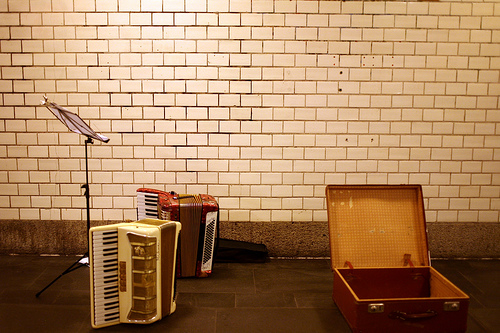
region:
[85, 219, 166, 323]
accordion on the ground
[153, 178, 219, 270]
brown accordion on the ground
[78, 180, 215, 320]
two accordions on the ground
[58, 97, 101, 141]
music sheet stand on ground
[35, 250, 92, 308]
bottom stand for pole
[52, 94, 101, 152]
white paper on music sheet stand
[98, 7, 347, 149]
white tile wall in the background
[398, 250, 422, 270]
brown latch on case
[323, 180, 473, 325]
brown suit case opened up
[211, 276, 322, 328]
grey stones on ground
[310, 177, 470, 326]
case for an instrument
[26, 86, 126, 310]
stand for sheet music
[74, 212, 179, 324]
keyboard to play music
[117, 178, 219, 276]
keyboard to play music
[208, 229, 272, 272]
sleeve to place instrument in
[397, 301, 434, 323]
handle on suitcase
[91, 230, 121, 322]
keys on the instrument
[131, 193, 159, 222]
keys on the instrument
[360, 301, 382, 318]
area for lock on suitcase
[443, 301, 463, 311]
area for lock on suitcase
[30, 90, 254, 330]
These are instruments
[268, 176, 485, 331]
The box is open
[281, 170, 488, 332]
The box is brown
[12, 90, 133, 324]
A musical stand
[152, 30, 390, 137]
White is the color of the wall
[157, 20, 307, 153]
Bricks on the wall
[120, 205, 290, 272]
A case on the ground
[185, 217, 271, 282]
The case is black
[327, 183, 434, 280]
This is an old case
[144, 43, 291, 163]
A white brick wall behind the instruments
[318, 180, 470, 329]
A brown suitcase by the instruments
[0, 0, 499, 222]
The white wall is made of bricks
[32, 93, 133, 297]
A black stand holding sheet music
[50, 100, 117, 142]
Sheet music on the black stand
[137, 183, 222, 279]
A red keyboard by the music stand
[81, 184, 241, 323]
Two keyboards lying on the ground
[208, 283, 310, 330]
A black floor beneath the instruments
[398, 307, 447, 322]
A brown handle on the suitcase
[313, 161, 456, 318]
brown case on floor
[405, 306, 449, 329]
brown handle on case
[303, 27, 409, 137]
white brick on wall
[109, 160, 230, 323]
two accordions on floor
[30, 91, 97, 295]
black stand with sheet music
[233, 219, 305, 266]
dark grey brick near floor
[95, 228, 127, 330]
black and white keys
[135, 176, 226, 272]
brown accordion near wall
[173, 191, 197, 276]
brown valves on accordion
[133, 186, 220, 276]
Mostly red accordian.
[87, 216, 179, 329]
A white and cream colored accordian.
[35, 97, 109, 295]
A black music stand.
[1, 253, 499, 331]
A grey concrete block walkway.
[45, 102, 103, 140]
White paper on a music stand.